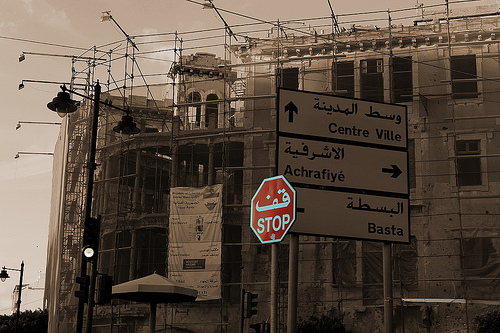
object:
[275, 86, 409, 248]
sign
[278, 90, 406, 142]
arabic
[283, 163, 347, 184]
roman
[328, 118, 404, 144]
two alphabets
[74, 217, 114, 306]
traffic light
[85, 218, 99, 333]
pole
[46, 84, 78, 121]
streetlight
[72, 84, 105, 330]
pole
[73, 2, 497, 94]
scaffold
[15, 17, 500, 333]
building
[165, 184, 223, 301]
banner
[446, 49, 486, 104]
window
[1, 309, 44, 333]
tree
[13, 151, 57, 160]
lights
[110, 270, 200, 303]
umbrella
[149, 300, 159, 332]
pole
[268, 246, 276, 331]
pole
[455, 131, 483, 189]
window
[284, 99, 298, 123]
arrow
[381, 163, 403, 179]
arrow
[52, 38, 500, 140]
top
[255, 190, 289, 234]
print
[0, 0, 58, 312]
sky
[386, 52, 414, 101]
windows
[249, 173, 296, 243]
stop sign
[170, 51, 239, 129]
tower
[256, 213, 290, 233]
stop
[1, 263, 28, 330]
streetlight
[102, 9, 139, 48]
light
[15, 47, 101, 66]
light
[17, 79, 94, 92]
light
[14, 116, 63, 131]
light